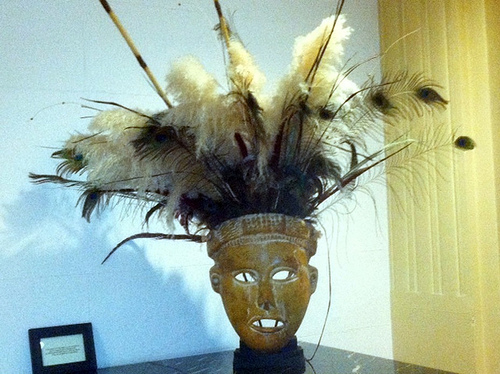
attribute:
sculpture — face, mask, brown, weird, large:
[206, 213, 331, 352]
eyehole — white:
[232, 267, 259, 285]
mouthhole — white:
[251, 315, 285, 331]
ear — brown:
[210, 266, 224, 295]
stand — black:
[231, 340, 304, 372]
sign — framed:
[28, 323, 98, 373]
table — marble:
[94, 351, 230, 374]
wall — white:
[2, 2, 161, 357]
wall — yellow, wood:
[377, 2, 499, 371]